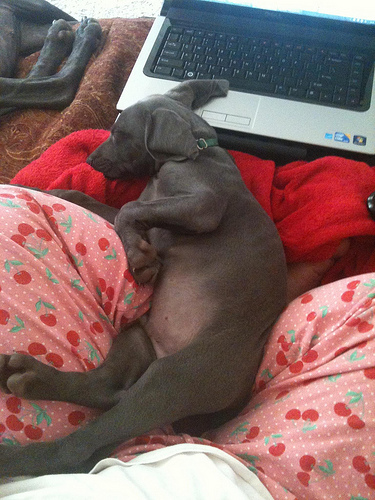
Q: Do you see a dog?
A: Yes, there is a dog.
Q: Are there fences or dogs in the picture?
A: Yes, there is a dog.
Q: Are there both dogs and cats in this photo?
A: No, there is a dog but no cats.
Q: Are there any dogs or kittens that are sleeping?
A: Yes, the dog is sleeping.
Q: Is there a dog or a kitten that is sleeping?
A: Yes, the dog is sleeping.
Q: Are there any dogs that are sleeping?
A: Yes, there is a dog that is sleeping.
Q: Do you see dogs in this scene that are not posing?
A: Yes, there is a dog that is sleeping .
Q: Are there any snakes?
A: No, there are no snakes.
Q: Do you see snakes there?
A: No, there are no snakes.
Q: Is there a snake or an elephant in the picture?
A: No, there are no snakes or elephants.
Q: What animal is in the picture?
A: The animal is a dog.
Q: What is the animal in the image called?
A: The animal is a dog.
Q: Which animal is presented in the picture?
A: The animal is a dog.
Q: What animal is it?
A: The animal is a dog.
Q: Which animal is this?
A: This is a dog.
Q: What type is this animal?
A: This is a dog.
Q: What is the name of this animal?
A: This is a dog.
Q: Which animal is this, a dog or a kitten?
A: This is a dog.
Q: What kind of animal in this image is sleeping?
A: The animal is a dog.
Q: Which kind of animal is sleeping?
A: The animal is a dog.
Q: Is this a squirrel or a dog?
A: This is a dog.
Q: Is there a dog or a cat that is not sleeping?
A: No, there is a dog but it is sleeping.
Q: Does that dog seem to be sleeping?
A: Yes, the dog is sleeping.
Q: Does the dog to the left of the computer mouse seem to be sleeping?
A: Yes, the dog is sleeping.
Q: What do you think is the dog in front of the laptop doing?
A: The dog is sleeping.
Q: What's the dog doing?
A: The dog is sleeping.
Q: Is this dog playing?
A: No, the dog is sleeping.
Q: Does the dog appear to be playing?
A: No, the dog is sleeping.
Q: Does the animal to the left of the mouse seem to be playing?
A: No, the dog is sleeping.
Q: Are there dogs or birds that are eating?
A: No, there is a dog but it is sleeping.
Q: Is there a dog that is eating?
A: No, there is a dog but it is sleeping.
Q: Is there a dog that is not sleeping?
A: No, there is a dog but it is sleeping.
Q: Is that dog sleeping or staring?
A: The dog is sleeping.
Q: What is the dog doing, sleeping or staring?
A: The dog is sleeping.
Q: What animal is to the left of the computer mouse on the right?
A: The animal is a dog.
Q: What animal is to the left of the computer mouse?
A: The animal is a dog.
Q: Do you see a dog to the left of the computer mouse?
A: Yes, there is a dog to the left of the computer mouse.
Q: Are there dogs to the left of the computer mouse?
A: Yes, there is a dog to the left of the computer mouse.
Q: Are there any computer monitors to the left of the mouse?
A: No, there is a dog to the left of the mouse.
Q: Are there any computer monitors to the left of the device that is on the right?
A: No, there is a dog to the left of the mouse.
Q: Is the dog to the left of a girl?
A: No, the dog is to the left of the mouse.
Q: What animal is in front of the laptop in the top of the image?
A: The dog is in front of the laptop computer.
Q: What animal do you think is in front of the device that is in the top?
A: The dog is in front of the laptop computer.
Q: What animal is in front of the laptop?
A: The dog is in front of the laptop computer.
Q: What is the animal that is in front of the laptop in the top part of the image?
A: The animal is a dog.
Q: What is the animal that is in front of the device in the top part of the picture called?
A: The animal is a dog.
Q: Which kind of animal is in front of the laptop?
A: The animal is a dog.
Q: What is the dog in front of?
A: The dog is in front of the laptop computer.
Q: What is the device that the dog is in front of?
A: The device is a laptop.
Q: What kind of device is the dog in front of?
A: The dog is in front of the laptop.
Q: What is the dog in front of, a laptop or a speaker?
A: The dog is in front of a laptop.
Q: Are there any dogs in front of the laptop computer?
A: Yes, there is a dog in front of the laptop computer.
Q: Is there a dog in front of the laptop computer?
A: Yes, there is a dog in front of the laptop computer.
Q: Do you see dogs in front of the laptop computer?
A: Yes, there is a dog in front of the laptop computer.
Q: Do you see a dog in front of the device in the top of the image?
A: Yes, there is a dog in front of the laptop computer.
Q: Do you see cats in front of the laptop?
A: No, there is a dog in front of the laptop.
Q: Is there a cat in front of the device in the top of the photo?
A: No, there is a dog in front of the laptop.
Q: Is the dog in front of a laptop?
A: Yes, the dog is in front of a laptop.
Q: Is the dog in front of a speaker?
A: No, the dog is in front of a laptop.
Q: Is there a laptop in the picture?
A: Yes, there is a laptop.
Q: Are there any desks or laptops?
A: Yes, there is a laptop.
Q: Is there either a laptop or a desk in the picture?
A: Yes, there is a laptop.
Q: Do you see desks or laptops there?
A: Yes, there is a laptop.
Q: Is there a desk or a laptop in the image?
A: Yes, there is a laptop.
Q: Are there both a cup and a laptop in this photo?
A: No, there is a laptop but no cups.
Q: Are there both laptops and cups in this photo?
A: No, there is a laptop but no cups.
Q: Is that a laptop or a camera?
A: That is a laptop.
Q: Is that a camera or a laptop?
A: That is a laptop.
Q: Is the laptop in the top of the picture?
A: Yes, the laptop is in the top of the image.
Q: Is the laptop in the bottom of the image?
A: No, the laptop is in the top of the image.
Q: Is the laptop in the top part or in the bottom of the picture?
A: The laptop is in the top of the image.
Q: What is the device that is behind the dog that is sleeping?
A: The device is a laptop.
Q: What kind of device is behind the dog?
A: The device is a laptop.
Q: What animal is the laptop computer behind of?
A: The laptop computer is behind the dog.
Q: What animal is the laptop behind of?
A: The laptop computer is behind the dog.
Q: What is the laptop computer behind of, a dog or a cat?
A: The laptop computer is behind a dog.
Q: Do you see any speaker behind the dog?
A: No, there is a laptop behind the dog.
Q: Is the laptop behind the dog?
A: Yes, the laptop is behind the dog.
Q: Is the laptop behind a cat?
A: No, the laptop is behind the dog.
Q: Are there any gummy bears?
A: No, there are no gummy bears.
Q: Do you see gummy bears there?
A: No, there are no gummy bears.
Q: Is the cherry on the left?
A: Yes, the cherry is on the left of the image.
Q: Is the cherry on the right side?
A: No, the cherry is on the left of the image.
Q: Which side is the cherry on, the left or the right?
A: The cherry is on the left of the image.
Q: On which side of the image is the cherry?
A: The cherry is on the left of the image.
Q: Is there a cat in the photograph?
A: No, there are no cats.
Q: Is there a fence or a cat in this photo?
A: No, there are no cats or fences.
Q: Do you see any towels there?
A: Yes, there is a towel.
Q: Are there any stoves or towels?
A: Yes, there is a towel.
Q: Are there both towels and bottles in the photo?
A: No, there is a towel but no bottles.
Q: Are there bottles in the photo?
A: No, there are no bottles.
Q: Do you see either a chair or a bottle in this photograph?
A: No, there are no bottles or chairs.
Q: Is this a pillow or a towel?
A: This is a towel.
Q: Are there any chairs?
A: No, there are no chairs.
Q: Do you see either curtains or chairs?
A: No, there are no chairs or curtains.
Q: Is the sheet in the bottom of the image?
A: Yes, the sheet is in the bottom of the image.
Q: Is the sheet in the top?
A: No, the sheet is in the bottom of the image.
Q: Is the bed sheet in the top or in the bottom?
A: The bed sheet is in the bottom of the image.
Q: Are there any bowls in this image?
A: No, there are no bowls.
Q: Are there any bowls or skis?
A: No, there are no bowls or skis.